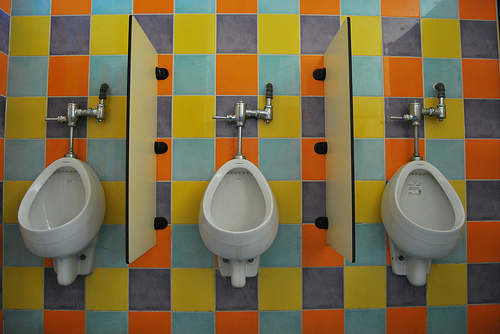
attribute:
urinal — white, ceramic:
[180, 130, 318, 295]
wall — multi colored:
[172, 16, 328, 66]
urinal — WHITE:
[8, 144, 105, 300]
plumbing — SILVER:
[36, 65, 126, 157]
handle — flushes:
[26, 87, 128, 179]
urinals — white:
[13, 77, 460, 297]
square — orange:
[213, 52, 258, 98]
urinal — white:
[8, 90, 110, 294]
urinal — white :
[198, 96, 280, 284]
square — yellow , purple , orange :
[217, 52, 256, 94]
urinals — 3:
[18, 90, 498, 285]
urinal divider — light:
[126, 15, 161, 270]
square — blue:
[152, 16, 244, 67]